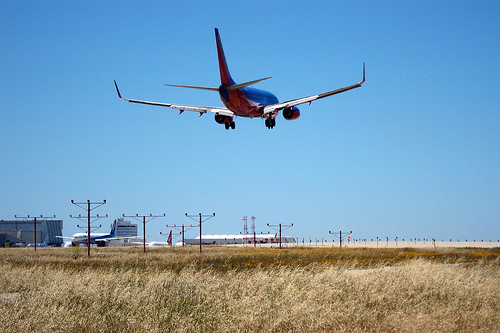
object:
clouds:
[85, 0, 500, 177]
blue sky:
[1, 0, 494, 232]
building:
[0, 215, 64, 248]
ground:
[0, 243, 494, 331]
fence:
[228, 237, 498, 248]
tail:
[191, 28, 252, 84]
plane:
[107, 26, 367, 131]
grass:
[2, 242, 498, 333]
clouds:
[195, 234, 294, 239]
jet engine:
[282, 107, 300, 121]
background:
[0, 142, 500, 250]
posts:
[34, 185, 500, 258]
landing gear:
[214, 112, 279, 130]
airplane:
[109, 27, 366, 129]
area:
[142, 270, 500, 333]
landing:
[21, 251, 298, 271]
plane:
[65, 243, 164, 249]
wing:
[110, 75, 368, 119]